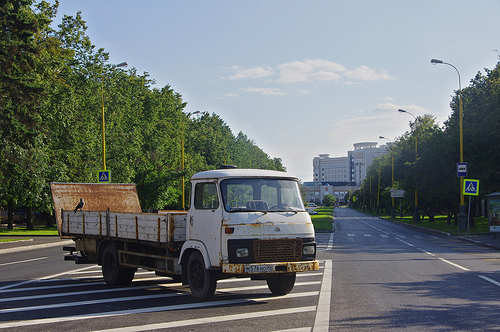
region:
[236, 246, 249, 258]
a square headlight on a truck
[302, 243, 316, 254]
a square headlight on a truck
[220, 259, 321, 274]
a rusty white and yellow bumper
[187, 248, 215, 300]
a black rubber tire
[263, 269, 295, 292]
a black rubber tire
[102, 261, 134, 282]
a black rubber tire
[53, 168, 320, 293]
a rusty old pick up truck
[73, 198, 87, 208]
a bird perched on a truck bed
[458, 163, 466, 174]
a blue and white sign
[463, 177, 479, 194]
a blue yellow and white sign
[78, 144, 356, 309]
Old truck with open trailer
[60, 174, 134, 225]
rust accumulated due to age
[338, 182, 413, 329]
recently paved street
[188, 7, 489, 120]
light blue sky signifying comfortable weather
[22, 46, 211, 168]
ample trees lining the street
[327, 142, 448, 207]
large building resembling a hotel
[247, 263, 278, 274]
old or out of state license plate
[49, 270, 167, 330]
cross hatched section barrier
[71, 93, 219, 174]
green tree leaves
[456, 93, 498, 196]
yellow painted street light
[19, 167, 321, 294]
a white rusty truck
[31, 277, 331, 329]
white lines on the street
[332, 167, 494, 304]
a long empty street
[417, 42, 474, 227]
a yellow street light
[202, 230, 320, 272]
a very rusty grill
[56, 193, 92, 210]
a black bird sitting on the truck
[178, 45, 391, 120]
clouds in the sky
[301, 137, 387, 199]
a big white building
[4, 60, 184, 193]
tall trees to the left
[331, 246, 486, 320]
shadow of the trees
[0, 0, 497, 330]
empty city street on sunny day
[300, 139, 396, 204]
buildings at end of street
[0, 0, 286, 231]
group of trees on left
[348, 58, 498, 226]
group of trees on right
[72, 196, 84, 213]
black bird on truck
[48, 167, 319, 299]
old abandoned rusty truck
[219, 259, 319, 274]
rusty bumper with license plate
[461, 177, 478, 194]
yellow and blue sign on right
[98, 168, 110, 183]
yellow and blue sign on left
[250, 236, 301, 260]
rusty grill on truck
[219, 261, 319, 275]
rusty bumper on truck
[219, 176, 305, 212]
large clear windshield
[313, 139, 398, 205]
large building at the end of the street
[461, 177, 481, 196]
square blue sign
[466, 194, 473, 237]
metal pole supporting blue sign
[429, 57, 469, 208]
yellow lamp post next to street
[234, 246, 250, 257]
headlight on truck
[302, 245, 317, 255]
headlight to the right of headlight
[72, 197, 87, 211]
black bird on the truck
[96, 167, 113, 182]
blue sign on lamp post